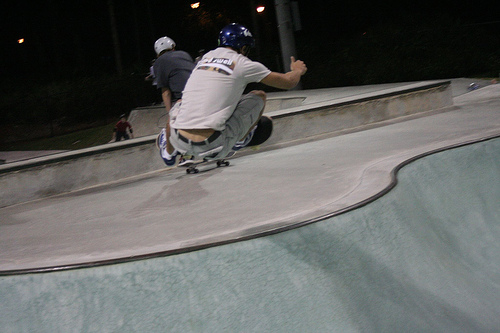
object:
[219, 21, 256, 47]
helmet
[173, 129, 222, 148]
belt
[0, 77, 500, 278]
pavement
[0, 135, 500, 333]
ramp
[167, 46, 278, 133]
shirt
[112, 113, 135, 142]
men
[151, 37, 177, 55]
cap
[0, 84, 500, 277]
road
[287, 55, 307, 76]
hand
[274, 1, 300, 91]
pillar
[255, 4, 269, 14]
light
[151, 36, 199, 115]
skateboarders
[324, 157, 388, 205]
curves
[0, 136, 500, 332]
surface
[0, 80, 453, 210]
rider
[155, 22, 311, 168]
skateboarder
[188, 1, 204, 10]
lights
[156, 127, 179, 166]
foot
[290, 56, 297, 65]
thumbs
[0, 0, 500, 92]
sky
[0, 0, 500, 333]
photo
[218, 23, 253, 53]
head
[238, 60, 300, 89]
arm